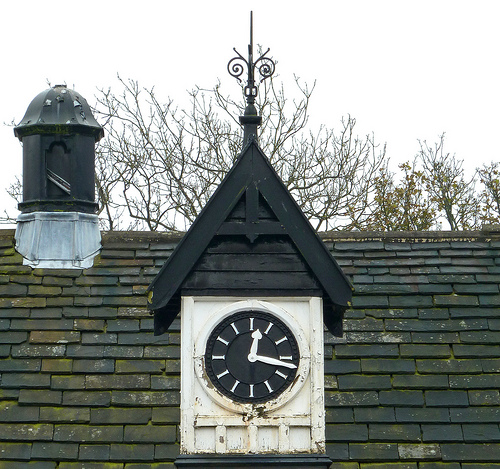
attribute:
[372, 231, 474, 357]
roof — BLACK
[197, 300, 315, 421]
clock — black, white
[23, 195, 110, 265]
cylinder — domed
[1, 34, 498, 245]
branches — bare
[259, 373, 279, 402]
number — white